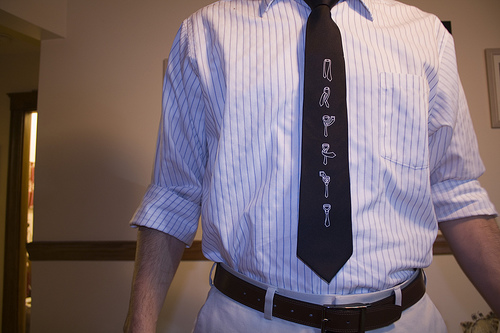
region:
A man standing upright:
[127, 1, 498, 331]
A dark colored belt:
[216, 265, 426, 330]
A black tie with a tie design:
[295, 1, 351, 283]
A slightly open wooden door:
[0, 33, 29, 331]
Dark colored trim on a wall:
[31, 237, 455, 262]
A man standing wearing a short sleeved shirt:
[125, 2, 497, 331]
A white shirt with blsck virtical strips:
[132, 2, 498, 293]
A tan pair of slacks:
[195, 267, 446, 332]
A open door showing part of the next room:
[3, 35, 42, 331]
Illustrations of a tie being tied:
[317, 59, 334, 228]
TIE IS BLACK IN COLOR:
[297, 2, 352, 282]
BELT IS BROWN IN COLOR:
[212, 257, 447, 327]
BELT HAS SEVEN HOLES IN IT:
[229, 285, 360, 330]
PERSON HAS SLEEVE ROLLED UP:
[128, 180, 200, 245]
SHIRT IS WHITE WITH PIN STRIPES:
[133, 0, 497, 300]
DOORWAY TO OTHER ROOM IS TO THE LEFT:
[6, 90, 33, 330]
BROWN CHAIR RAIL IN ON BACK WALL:
[29, 243, 203, 265]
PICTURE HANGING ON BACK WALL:
[481, 43, 498, 143]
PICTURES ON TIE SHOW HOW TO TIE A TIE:
[316, 55, 335, 227]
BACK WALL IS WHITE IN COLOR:
[41, 42, 150, 236]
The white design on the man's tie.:
[311, 48, 348, 243]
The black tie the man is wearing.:
[303, 1, 350, 281]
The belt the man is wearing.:
[214, 269, 434, 331]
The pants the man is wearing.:
[197, 269, 444, 331]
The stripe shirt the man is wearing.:
[172, 8, 473, 283]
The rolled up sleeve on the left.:
[132, 188, 196, 243]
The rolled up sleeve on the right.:
[434, 179, 493, 219]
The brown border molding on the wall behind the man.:
[24, 239, 499, 261]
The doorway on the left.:
[18, 108, 31, 325]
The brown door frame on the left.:
[7, 87, 41, 332]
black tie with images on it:
[305, 5, 358, 276]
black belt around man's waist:
[210, 279, 444, 316]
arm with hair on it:
[135, 224, 185, 331]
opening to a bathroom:
[8, 92, 50, 322]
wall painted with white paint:
[43, 39, 142, 239]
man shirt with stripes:
[168, 25, 465, 290]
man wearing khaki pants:
[211, 267, 454, 332]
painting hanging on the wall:
[479, 49, 499, 120]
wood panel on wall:
[28, 243, 203, 261]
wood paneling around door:
[8, 94, 20, 331]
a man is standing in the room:
[116, 1, 498, 331]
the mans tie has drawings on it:
[297, 1, 357, 281]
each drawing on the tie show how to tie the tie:
[309, 32, 347, 236]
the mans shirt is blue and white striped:
[134, 0, 499, 311]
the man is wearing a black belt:
[205, 261, 440, 328]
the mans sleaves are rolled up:
[141, 8, 218, 257]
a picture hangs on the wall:
[481, 45, 498, 132]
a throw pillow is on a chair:
[466, 311, 499, 331]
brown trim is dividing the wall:
[26, 240, 133, 260]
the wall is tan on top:
[39, 40, 155, 242]